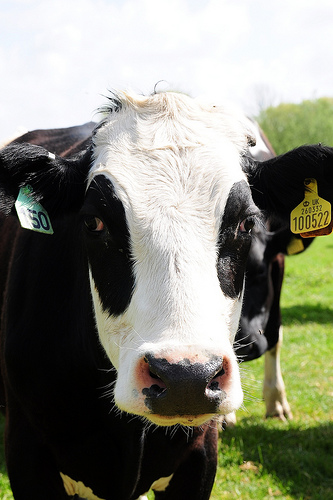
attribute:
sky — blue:
[4, 4, 327, 96]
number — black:
[320, 198, 330, 228]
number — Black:
[293, 202, 332, 228]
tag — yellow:
[285, 176, 332, 233]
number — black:
[292, 209, 328, 230]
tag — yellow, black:
[290, 178, 331, 235]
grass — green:
[272, 235, 330, 366]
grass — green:
[219, 430, 332, 498]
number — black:
[310, 212, 317, 228]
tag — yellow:
[284, 178, 331, 238]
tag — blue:
[9, 176, 61, 234]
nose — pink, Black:
[131, 348, 231, 417]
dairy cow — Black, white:
[0, 89, 331, 499]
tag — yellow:
[273, 173, 332, 243]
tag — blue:
[8, 178, 56, 239]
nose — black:
[140, 346, 231, 417]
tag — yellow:
[286, 186, 330, 237]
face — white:
[56, 95, 288, 428]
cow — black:
[9, 133, 325, 485]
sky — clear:
[64, 12, 328, 63]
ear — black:
[2, 137, 80, 246]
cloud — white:
[17, 3, 101, 49]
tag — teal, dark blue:
[10, 186, 55, 236]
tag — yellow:
[278, 171, 331, 235]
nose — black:
[137, 359, 221, 417]